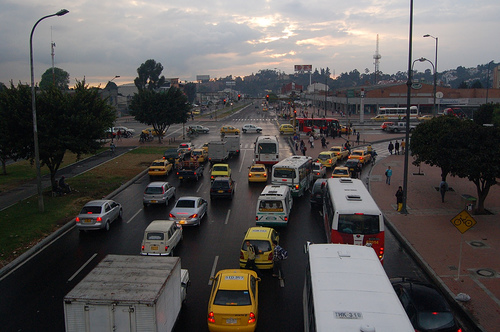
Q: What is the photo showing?
A: It is showing a street.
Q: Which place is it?
A: It is a street.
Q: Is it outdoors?
A: Yes, it is outdoors.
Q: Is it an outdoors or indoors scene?
A: It is outdoors.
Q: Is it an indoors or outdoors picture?
A: It is outdoors.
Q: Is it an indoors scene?
A: No, it is outdoors.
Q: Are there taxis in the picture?
A: Yes, there is a taxi.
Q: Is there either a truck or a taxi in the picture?
A: Yes, there is a taxi.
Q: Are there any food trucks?
A: No, there are no food trucks.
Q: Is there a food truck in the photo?
A: No, there are no food trucks.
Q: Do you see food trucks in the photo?
A: No, there are no food trucks.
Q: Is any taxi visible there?
A: Yes, there is a taxi.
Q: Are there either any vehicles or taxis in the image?
A: Yes, there is a taxi.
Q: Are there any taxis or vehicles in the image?
A: Yes, there is a taxi.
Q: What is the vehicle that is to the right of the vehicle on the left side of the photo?
A: The vehicle is a taxi.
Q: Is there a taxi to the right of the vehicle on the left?
A: Yes, there is a taxi to the right of the vehicle.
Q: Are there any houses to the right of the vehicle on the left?
A: No, there is a taxi to the right of the vehicle.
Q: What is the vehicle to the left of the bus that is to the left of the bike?
A: The vehicle is a taxi.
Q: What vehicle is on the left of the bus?
A: The vehicle is a taxi.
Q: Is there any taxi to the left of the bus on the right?
A: Yes, there is a taxi to the left of the bus.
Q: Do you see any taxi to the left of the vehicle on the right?
A: Yes, there is a taxi to the left of the bus.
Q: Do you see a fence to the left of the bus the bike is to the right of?
A: No, there is a taxi to the left of the bus.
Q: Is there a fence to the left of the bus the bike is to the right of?
A: No, there is a taxi to the left of the bus.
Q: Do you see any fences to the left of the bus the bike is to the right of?
A: No, there is a taxi to the left of the bus.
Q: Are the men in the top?
A: No, the men are in the bottom of the image.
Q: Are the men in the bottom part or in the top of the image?
A: The men are in the bottom of the image.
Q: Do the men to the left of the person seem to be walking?
A: Yes, the men are walking.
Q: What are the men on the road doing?
A: The men are walking.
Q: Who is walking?
A: The men are walking.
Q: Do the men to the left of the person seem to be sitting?
A: No, the men are walking.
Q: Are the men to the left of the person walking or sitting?
A: The men are walking.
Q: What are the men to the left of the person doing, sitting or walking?
A: The men are walking.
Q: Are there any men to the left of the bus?
A: Yes, there are men to the left of the bus.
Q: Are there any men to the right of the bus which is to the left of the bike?
A: No, the men are to the left of the bus.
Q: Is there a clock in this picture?
A: No, there are no clocks.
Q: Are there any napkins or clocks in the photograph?
A: No, there are no clocks or napkins.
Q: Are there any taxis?
A: Yes, there is a taxi.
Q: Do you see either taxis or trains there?
A: Yes, there is a taxi.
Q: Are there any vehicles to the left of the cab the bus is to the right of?
A: Yes, there is a vehicle to the left of the cab.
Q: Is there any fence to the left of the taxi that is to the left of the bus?
A: No, there is a vehicle to the left of the cab.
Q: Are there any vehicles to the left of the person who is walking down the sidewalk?
A: Yes, there is a vehicle to the left of the person.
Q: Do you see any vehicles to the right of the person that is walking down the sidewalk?
A: No, the vehicle is to the left of the person.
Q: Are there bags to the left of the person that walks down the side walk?
A: No, there is a vehicle to the left of the person.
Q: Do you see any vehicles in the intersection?
A: Yes, there is a vehicle in the intersection.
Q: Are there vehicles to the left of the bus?
A: Yes, there is a vehicle to the left of the bus.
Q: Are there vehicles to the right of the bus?
A: No, the vehicle is to the left of the bus.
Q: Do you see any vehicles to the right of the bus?
A: No, the vehicle is to the left of the bus.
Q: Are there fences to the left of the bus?
A: No, there is a vehicle to the left of the bus.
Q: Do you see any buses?
A: Yes, there is a bus.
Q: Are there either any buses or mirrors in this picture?
A: Yes, there is a bus.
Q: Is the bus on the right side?
A: Yes, the bus is on the right of the image.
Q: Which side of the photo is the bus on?
A: The bus is on the right of the image.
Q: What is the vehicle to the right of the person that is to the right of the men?
A: The vehicle is a bus.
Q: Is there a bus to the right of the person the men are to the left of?
A: Yes, there is a bus to the right of the person.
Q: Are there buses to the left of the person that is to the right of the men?
A: No, the bus is to the right of the person.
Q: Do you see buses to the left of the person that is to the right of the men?
A: No, the bus is to the right of the person.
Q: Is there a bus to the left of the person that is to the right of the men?
A: No, the bus is to the right of the person.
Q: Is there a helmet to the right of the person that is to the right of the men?
A: No, there is a bus to the right of the person.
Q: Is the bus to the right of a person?
A: Yes, the bus is to the right of a person.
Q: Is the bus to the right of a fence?
A: No, the bus is to the right of a person.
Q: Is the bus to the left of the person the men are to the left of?
A: No, the bus is to the right of the person.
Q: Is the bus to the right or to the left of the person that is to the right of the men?
A: The bus is to the right of the person.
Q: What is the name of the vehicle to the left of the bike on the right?
A: The vehicle is a bus.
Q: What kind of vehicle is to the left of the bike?
A: The vehicle is a bus.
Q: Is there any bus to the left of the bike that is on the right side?
A: Yes, there is a bus to the left of the bike.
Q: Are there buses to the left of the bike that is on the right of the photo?
A: Yes, there is a bus to the left of the bike.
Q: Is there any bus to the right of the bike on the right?
A: No, the bus is to the left of the bike.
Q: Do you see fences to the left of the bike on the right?
A: No, there is a bus to the left of the bike.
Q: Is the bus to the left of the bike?
A: Yes, the bus is to the left of the bike.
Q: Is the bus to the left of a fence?
A: No, the bus is to the left of the bike.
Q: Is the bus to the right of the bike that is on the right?
A: No, the bus is to the left of the bike.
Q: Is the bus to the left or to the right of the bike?
A: The bus is to the left of the bike.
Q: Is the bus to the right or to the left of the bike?
A: The bus is to the left of the bike.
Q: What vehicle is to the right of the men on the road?
A: The vehicle is a bus.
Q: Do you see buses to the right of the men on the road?
A: Yes, there is a bus to the right of the men.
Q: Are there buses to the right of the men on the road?
A: Yes, there is a bus to the right of the men.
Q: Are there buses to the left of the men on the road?
A: No, the bus is to the right of the men.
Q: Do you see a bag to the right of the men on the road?
A: No, there is a bus to the right of the men.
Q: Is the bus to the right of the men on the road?
A: Yes, the bus is to the right of the men.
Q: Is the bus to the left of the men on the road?
A: No, the bus is to the right of the men.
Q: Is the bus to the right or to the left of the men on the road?
A: The bus is to the right of the men.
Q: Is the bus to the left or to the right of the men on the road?
A: The bus is to the right of the men.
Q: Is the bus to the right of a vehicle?
A: Yes, the bus is to the right of a vehicle.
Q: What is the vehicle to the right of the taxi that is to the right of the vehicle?
A: The vehicle is a bus.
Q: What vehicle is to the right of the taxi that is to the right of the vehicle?
A: The vehicle is a bus.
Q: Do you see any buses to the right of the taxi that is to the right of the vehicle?
A: Yes, there is a bus to the right of the taxi.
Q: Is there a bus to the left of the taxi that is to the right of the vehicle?
A: No, the bus is to the right of the taxi.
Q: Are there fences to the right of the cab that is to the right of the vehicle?
A: No, there is a bus to the right of the taxi.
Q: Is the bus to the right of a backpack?
A: No, the bus is to the right of the taxi.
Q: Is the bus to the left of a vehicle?
A: No, the bus is to the right of a vehicle.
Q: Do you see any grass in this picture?
A: Yes, there is grass.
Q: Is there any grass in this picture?
A: Yes, there is grass.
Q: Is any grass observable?
A: Yes, there is grass.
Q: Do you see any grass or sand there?
A: Yes, there is grass.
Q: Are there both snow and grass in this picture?
A: No, there is grass but no snow.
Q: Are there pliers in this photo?
A: No, there are no pliers.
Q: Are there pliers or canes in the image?
A: No, there are no pliers or canes.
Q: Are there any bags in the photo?
A: No, there are no bags.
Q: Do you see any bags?
A: No, there are no bags.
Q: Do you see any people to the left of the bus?
A: Yes, there is a person to the left of the bus.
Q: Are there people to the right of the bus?
A: No, the person is to the left of the bus.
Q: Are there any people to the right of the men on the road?
A: Yes, there is a person to the right of the men.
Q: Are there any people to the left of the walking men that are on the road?
A: No, the person is to the right of the men.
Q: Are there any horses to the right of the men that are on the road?
A: No, there is a person to the right of the men.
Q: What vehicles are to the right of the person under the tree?
A: The vehicles are cars.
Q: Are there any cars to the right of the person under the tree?
A: Yes, there are cars to the right of the person.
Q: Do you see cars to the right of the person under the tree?
A: Yes, there are cars to the right of the person.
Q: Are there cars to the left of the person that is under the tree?
A: No, the cars are to the right of the person.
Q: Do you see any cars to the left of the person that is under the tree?
A: No, the cars are to the right of the person.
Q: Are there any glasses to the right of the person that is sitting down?
A: No, there are cars to the right of the person.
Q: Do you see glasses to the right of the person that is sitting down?
A: No, there are cars to the right of the person.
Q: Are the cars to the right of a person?
A: Yes, the cars are to the right of a person.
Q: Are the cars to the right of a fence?
A: No, the cars are to the right of a person.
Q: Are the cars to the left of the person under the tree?
A: No, the cars are to the right of the person.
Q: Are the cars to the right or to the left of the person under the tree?
A: The cars are to the right of the person.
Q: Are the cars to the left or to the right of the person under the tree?
A: The cars are to the right of the person.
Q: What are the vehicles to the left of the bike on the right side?
A: The vehicles are cars.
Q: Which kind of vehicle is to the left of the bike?
A: The vehicles are cars.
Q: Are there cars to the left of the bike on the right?
A: Yes, there are cars to the left of the bike.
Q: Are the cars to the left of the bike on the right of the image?
A: Yes, the cars are to the left of the bike.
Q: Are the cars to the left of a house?
A: No, the cars are to the left of the bike.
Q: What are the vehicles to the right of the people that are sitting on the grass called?
A: The vehicles are cars.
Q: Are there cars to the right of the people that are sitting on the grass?
A: Yes, there are cars to the right of the people.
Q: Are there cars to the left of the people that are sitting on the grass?
A: No, the cars are to the right of the people.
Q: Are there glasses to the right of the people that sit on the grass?
A: No, there are cars to the right of the people.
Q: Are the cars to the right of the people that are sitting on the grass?
A: Yes, the cars are to the right of the people.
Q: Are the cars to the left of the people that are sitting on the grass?
A: No, the cars are to the right of the people.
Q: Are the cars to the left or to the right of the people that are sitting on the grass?
A: The cars are to the right of the people.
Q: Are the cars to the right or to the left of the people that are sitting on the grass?
A: The cars are to the right of the people.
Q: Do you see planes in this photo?
A: No, there are no planes.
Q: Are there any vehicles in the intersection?
A: Yes, there is a vehicle in the intersection.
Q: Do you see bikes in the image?
A: Yes, there is a bike.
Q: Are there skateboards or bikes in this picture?
A: Yes, there is a bike.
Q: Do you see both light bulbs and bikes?
A: No, there is a bike but no light bulbs.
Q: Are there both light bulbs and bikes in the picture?
A: No, there is a bike but no light bulbs.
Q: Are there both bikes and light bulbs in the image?
A: No, there is a bike but no light bulbs.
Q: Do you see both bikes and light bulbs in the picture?
A: No, there is a bike but no light bulbs.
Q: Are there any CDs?
A: No, there are no cds.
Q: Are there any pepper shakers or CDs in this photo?
A: No, there are no CDs or pepper shakers.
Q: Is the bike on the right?
A: Yes, the bike is on the right of the image.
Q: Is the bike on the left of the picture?
A: No, the bike is on the right of the image.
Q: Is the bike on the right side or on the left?
A: The bike is on the right of the image.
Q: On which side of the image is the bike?
A: The bike is on the right of the image.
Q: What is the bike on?
A: The bike is on the sign.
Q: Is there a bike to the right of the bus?
A: Yes, there is a bike to the right of the bus.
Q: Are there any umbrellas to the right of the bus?
A: No, there is a bike to the right of the bus.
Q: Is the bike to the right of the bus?
A: Yes, the bike is to the right of the bus.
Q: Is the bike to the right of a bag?
A: No, the bike is to the right of the bus.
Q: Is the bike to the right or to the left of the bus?
A: The bike is to the right of the bus.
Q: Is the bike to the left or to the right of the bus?
A: The bike is to the right of the bus.